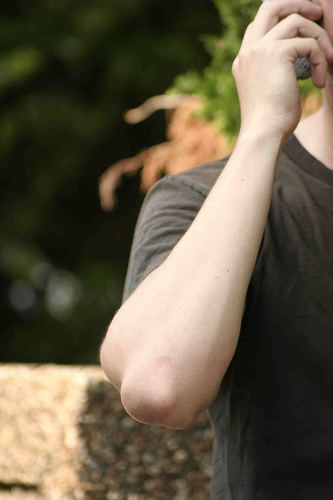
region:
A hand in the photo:
[155, 234, 229, 328]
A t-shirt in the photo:
[247, 344, 314, 462]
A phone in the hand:
[276, 43, 315, 83]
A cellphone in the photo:
[251, 41, 326, 91]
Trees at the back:
[178, 76, 223, 125]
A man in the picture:
[153, 209, 325, 407]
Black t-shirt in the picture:
[260, 326, 312, 450]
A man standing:
[237, 275, 327, 461]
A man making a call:
[240, 29, 331, 203]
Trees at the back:
[78, 55, 129, 123]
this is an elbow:
[99, 328, 222, 458]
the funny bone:
[92, 351, 184, 455]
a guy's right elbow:
[84, 320, 224, 445]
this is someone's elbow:
[93, 301, 254, 450]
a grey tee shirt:
[104, 120, 331, 498]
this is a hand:
[190, 2, 329, 154]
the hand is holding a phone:
[206, 0, 330, 153]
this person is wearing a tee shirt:
[90, 2, 332, 499]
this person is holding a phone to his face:
[105, 2, 325, 499]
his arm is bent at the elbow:
[77, 2, 331, 499]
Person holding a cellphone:
[233, 16, 313, 72]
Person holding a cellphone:
[258, 14, 332, 97]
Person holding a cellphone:
[245, 13, 324, 84]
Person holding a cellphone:
[250, 14, 331, 89]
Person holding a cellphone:
[245, 13, 329, 83]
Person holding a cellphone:
[239, 2, 332, 76]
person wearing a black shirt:
[246, 417, 327, 445]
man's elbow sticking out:
[116, 371, 180, 428]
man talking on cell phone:
[80, 0, 330, 497]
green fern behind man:
[169, 4, 325, 156]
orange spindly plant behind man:
[80, 83, 229, 203]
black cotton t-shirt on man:
[120, 122, 330, 494]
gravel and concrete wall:
[1, 363, 220, 498]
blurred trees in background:
[0, 1, 214, 367]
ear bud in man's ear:
[279, 0, 327, 84]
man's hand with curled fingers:
[223, 1, 332, 136]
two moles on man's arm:
[207, 265, 236, 283]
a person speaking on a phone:
[103, 0, 328, 499]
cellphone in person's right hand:
[236, 11, 331, 122]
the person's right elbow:
[118, 373, 178, 423]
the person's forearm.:
[112, 137, 271, 426]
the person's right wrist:
[238, 120, 289, 152]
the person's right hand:
[232, 4, 329, 129]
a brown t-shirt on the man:
[126, 133, 326, 495]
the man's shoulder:
[135, 115, 332, 237]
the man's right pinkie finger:
[286, 41, 326, 88]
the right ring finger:
[272, 13, 332, 58]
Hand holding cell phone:
[234, 9, 330, 139]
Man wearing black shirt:
[135, 138, 329, 490]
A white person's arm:
[99, 0, 331, 429]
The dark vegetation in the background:
[0, 1, 320, 364]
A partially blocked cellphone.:
[296, 51, 312, 78]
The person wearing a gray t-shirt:
[101, 1, 332, 499]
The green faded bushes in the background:
[176, 0, 320, 140]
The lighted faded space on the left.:
[0, 365, 104, 498]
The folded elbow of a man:
[101, 332, 235, 427]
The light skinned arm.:
[87, 0, 332, 499]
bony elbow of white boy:
[98, 344, 190, 433]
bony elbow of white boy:
[101, 346, 204, 435]